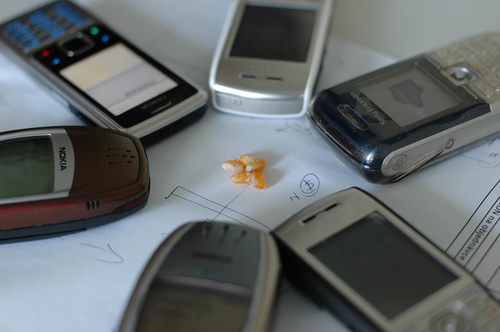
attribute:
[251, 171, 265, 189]
kernel — yellow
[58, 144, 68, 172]
nokia — black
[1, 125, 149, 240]
phone — red, nokia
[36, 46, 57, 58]
button — red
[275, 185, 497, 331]
phone — green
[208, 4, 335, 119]
mobile — grey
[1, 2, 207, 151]
phone — black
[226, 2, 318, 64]
screen — dark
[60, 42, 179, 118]
screen — glowing, lit, bright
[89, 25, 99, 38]
button — green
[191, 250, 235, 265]
letters — black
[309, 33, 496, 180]
phone — grey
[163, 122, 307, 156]
paper — white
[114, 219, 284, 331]
phone — silver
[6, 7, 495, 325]
phones — old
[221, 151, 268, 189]
kernels — yellow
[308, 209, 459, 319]
screen — blank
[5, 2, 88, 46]
buttons — numbers, blue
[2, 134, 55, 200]
screen — blank